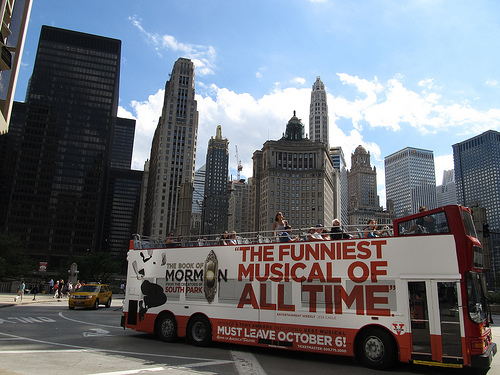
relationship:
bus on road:
[117, 197, 494, 374] [2, 286, 499, 374]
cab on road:
[66, 275, 115, 316] [2, 286, 499, 374]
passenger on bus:
[164, 230, 178, 244] [117, 197, 494, 374]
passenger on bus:
[177, 233, 187, 244] [117, 197, 494, 374]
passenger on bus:
[218, 228, 230, 244] [117, 197, 494, 374]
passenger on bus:
[230, 230, 244, 243] [117, 197, 494, 374]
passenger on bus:
[272, 210, 290, 236] [117, 197, 494, 374]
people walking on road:
[17, 275, 72, 302] [2, 286, 499, 374]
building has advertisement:
[35, 20, 124, 303] [37, 257, 51, 276]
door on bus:
[408, 280, 433, 355] [117, 197, 494, 374]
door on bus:
[433, 278, 472, 364] [117, 197, 494, 374]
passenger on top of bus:
[272, 210, 290, 236] [117, 197, 494, 374]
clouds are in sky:
[129, 62, 483, 163] [26, 2, 497, 160]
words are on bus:
[230, 239, 400, 319] [117, 197, 494, 374]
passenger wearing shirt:
[272, 210, 290, 236] [275, 221, 289, 232]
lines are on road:
[56, 309, 123, 333] [2, 286, 499, 374]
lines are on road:
[4, 331, 237, 367] [2, 286, 499, 374]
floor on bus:
[132, 225, 461, 247] [117, 197, 494, 374]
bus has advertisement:
[117, 197, 494, 374] [141, 242, 399, 319]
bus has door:
[117, 197, 494, 374] [408, 280, 433, 355]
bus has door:
[117, 197, 494, 374] [433, 278, 472, 364]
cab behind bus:
[66, 275, 115, 316] [117, 197, 494, 374]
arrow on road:
[81, 325, 114, 340] [2, 286, 499, 374]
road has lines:
[2, 286, 499, 374] [56, 309, 123, 333]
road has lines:
[2, 286, 499, 374] [4, 331, 237, 367]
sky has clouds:
[26, 2, 497, 160] [129, 62, 483, 163]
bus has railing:
[117, 197, 494, 374] [136, 219, 397, 241]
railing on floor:
[136, 219, 397, 241] [132, 225, 461, 247]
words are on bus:
[162, 284, 208, 295] [117, 197, 494, 374]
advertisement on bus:
[37, 257, 51, 276] [117, 197, 494, 374]